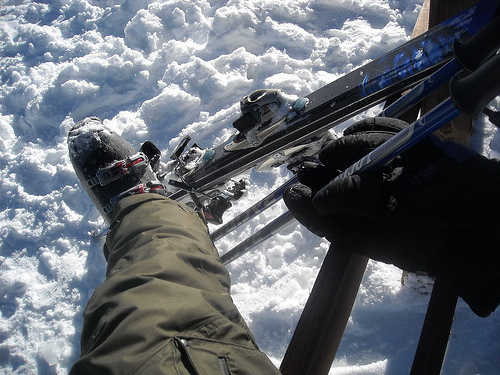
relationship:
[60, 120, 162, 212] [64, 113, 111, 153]
boot has snow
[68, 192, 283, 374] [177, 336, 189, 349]
pants have button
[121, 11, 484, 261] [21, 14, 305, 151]
skis have snow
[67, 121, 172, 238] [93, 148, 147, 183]
boot has latch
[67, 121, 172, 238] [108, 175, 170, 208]
boot has latch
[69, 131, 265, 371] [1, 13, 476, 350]
leg in snow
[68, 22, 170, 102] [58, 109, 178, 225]
snow on boot